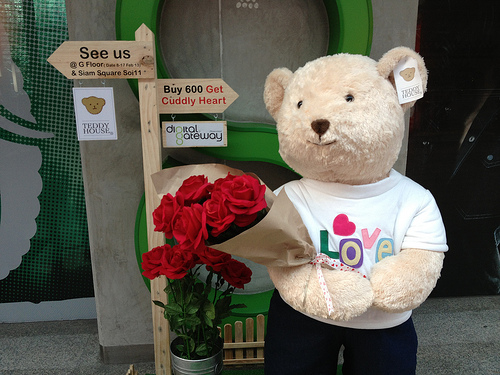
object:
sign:
[162, 121, 226, 146]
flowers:
[197, 247, 234, 273]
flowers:
[172, 243, 202, 264]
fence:
[218, 312, 264, 365]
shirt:
[271, 166, 451, 334]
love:
[317, 226, 398, 268]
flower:
[170, 199, 211, 250]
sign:
[66, 41, 152, 78]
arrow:
[154, 77, 239, 116]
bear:
[259, 43, 449, 372]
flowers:
[158, 245, 196, 281]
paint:
[0, 140, 44, 284]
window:
[1, 0, 93, 305]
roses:
[139, 242, 174, 282]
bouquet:
[151, 167, 371, 282]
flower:
[217, 174, 264, 217]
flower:
[175, 173, 213, 206]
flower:
[149, 191, 180, 239]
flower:
[200, 197, 236, 236]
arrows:
[44, 39, 153, 80]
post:
[132, 36, 173, 374]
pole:
[138, 78, 173, 374]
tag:
[391, 58, 425, 106]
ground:
[334, 89, 385, 139]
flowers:
[216, 257, 254, 289]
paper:
[149, 163, 320, 270]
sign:
[158, 79, 228, 109]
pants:
[262, 286, 419, 374]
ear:
[376, 43, 431, 110]